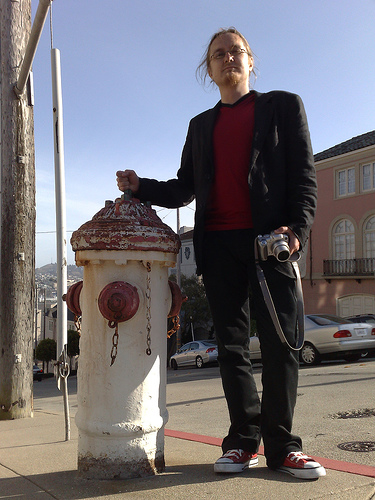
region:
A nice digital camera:
[255, 231, 315, 349]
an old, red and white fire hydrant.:
[63, 195, 187, 486]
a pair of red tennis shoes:
[214, 448, 324, 487]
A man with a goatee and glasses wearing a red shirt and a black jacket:
[114, 28, 326, 478]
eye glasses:
[207, 46, 253, 58]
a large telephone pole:
[4, 0, 44, 420]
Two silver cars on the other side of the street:
[181, 308, 373, 365]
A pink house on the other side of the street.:
[303, 146, 373, 329]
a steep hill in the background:
[37, 260, 85, 305]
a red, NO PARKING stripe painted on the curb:
[160, 420, 373, 483]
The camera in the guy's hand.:
[257, 229, 297, 265]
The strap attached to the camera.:
[253, 253, 317, 353]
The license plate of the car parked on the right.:
[351, 328, 368, 337]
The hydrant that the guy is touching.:
[53, 178, 176, 476]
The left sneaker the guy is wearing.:
[206, 445, 255, 475]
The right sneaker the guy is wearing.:
[270, 436, 327, 489]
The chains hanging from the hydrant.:
[102, 273, 164, 361]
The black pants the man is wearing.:
[201, 232, 319, 455]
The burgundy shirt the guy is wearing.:
[205, 96, 271, 233]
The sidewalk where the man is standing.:
[3, 409, 371, 498]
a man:
[119, 30, 330, 484]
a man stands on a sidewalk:
[118, 22, 341, 480]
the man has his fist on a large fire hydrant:
[63, 23, 334, 481]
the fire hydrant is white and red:
[65, 180, 198, 483]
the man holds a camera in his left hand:
[252, 222, 313, 352]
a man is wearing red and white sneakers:
[116, 22, 329, 475]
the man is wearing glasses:
[123, 18, 315, 454]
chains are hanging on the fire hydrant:
[63, 255, 180, 362]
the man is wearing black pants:
[135, 21, 327, 452]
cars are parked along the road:
[167, 307, 369, 369]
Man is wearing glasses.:
[210, 46, 254, 61]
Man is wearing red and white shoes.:
[217, 444, 335, 479]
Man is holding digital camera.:
[244, 227, 312, 284]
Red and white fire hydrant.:
[68, 201, 188, 483]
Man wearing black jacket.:
[189, 91, 313, 222]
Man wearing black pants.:
[208, 273, 312, 449]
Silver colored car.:
[308, 312, 372, 368]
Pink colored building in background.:
[313, 137, 374, 337]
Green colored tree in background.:
[33, 331, 57, 390]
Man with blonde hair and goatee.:
[186, 27, 282, 135]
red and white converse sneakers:
[178, 419, 349, 490]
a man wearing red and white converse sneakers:
[182, 12, 340, 483]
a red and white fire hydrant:
[54, 163, 209, 450]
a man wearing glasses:
[182, 12, 283, 122]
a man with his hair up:
[179, 18, 267, 99]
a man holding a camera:
[177, 11, 325, 294]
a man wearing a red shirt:
[174, 12, 321, 240]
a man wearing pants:
[174, 16, 335, 468]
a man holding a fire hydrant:
[36, 14, 327, 328]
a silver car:
[169, 333, 256, 384]